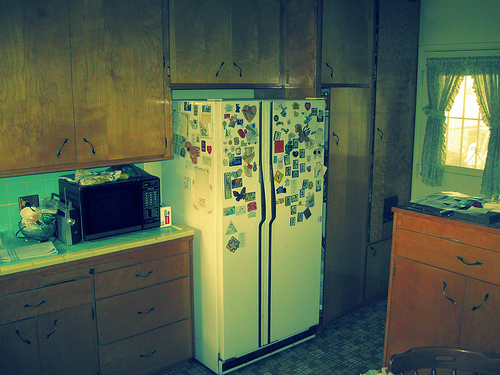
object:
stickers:
[223, 236, 241, 255]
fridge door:
[215, 96, 327, 360]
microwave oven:
[56, 164, 162, 244]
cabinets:
[0, 6, 173, 173]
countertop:
[2, 222, 191, 273]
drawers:
[97, 274, 197, 344]